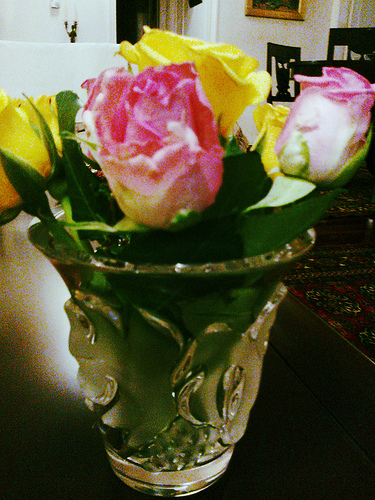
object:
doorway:
[115, 1, 158, 45]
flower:
[72, 60, 225, 228]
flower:
[0, 86, 63, 212]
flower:
[118, 26, 272, 138]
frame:
[244, 0, 308, 21]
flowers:
[249, 102, 289, 178]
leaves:
[227, 136, 368, 256]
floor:
[308, 214, 374, 296]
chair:
[324, 27, 374, 84]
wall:
[0, 0, 140, 104]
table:
[0, 190, 375, 500]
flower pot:
[25, 220, 317, 500]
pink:
[96, 82, 178, 177]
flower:
[274, 65, 374, 188]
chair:
[265, 41, 302, 107]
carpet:
[281, 180, 375, 365]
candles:
[64, 9, 79, 22]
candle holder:
[63, 21, 79, 43]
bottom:
[103, 443, 235, 499]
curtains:
[158, 0, 186, 37]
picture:
[240, 0, 305, 21]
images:
[63, 279, 290, 474]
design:
[63, 279, 290, 452]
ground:
[319, 215, 375, 301]